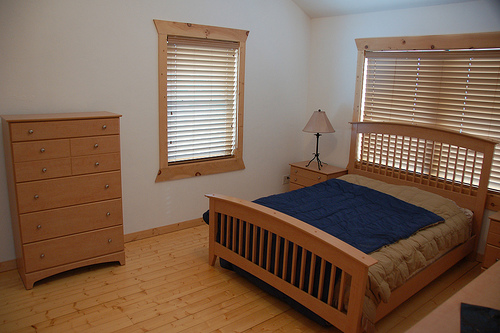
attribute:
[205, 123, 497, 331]
bed — light brown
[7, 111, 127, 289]
dresser — tall, wooden, large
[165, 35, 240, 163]
window — small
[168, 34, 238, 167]
window shade — tan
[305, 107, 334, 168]
lamp — black, brown, small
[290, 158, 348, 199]
night stand — brown, wooden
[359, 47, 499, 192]
window — large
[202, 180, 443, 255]
blanket — blue, navy blue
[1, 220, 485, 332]
floor — light brown, wooden, pine hardwood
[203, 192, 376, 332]
foot board — light brown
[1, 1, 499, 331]
bedroom — neat, plainly decorated, room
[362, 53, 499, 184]
blinds — closed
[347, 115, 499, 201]
head board — wooden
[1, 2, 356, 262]
wall — white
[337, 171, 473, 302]
bed cover — brown, beige